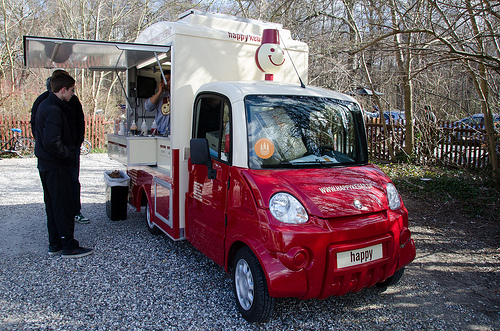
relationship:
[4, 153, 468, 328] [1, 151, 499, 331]
pebbles on ground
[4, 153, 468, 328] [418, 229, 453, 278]
pebbles on ground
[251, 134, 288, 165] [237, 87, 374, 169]
decal on windshield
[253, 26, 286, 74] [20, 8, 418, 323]
smiley face on truck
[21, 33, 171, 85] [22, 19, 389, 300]
side door on truck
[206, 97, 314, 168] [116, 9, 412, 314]
boxes inside truck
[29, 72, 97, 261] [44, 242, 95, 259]
man wearing shoes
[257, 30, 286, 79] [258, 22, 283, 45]
doll wearing red hat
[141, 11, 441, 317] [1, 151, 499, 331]
truck on ground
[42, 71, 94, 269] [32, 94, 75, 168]
man wearing shirt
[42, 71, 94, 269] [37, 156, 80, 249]
man wearing pants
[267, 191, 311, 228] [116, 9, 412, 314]
headlight on truck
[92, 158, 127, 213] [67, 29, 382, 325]
garbage can next to truck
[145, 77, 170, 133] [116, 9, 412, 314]
man working in truck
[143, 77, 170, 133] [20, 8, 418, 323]
man working in truck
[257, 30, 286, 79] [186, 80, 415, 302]
doll atop truck